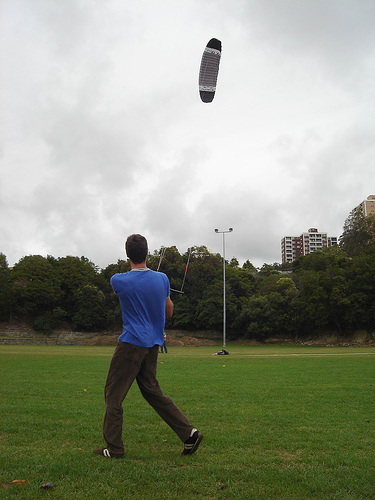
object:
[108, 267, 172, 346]
shirt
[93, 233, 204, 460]
man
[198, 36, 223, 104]
kite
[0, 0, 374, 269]
sky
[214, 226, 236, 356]
light pole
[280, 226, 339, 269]
building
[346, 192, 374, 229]
building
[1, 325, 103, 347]
wall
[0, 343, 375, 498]
field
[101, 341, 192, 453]
pants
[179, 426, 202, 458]
shoe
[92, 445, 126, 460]
shoe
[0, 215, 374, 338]
trees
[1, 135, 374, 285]
background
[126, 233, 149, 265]
hair